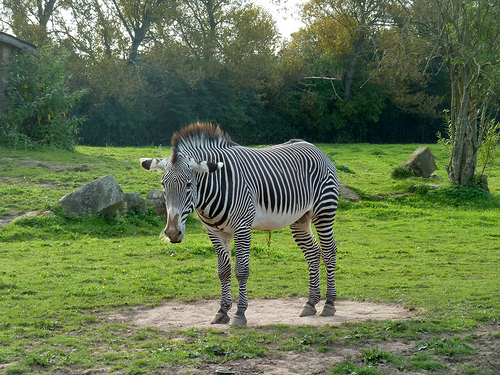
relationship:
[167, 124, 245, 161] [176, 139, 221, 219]
main on neck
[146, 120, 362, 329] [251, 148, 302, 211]
zebra has stripes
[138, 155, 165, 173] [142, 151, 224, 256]
ear on head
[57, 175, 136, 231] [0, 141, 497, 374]
stone on ground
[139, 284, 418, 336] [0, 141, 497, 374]
dirt on ground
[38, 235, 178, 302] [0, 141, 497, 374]
grass on ground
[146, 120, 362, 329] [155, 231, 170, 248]
zebra has whiskers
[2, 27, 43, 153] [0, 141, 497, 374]
building on ground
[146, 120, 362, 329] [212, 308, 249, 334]
zebra has hooves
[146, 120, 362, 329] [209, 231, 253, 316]
zebra has legs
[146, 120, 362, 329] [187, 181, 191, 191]
zebra has eye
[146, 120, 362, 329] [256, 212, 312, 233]
zebra has belly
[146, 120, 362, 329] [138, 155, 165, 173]
zebra has ear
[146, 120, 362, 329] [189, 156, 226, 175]
zebra has ear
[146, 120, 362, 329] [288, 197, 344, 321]
zebra has legs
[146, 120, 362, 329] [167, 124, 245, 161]
zebra has main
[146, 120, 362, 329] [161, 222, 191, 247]
zebra has nose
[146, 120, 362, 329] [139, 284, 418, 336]
zebra stands on dirt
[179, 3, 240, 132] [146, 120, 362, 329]
tree behind zebra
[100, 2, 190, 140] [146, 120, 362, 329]
tree behind zebra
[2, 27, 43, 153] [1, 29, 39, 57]
building has roof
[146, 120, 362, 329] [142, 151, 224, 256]
zebra has head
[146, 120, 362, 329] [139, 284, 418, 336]
zebra on dirt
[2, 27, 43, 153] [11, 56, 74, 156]
building behind bush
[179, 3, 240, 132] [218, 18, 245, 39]
tree has branches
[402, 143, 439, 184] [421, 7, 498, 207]
rock near tree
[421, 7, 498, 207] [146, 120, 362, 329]
tree behind zebra